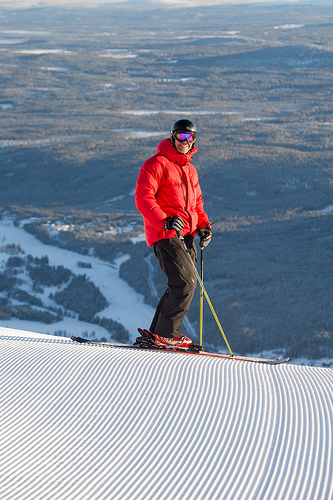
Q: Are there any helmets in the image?
A: Yes, there is a helmet.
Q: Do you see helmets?
A: Yes, there is a helmet.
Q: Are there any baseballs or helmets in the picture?
A: Yes, there is a helmet.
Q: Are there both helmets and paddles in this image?
A: No, there is a helmet but no paddles.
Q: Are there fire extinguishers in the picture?
A: No, there are no fire extinguishers.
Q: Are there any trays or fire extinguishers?
A: No, there are no fire extinguishers or trays.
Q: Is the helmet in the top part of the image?
A: Yes, the helmet is in the top of the image.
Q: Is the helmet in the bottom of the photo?
A: No, the helmet is in the top of the image.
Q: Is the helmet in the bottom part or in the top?
A: The helmet is in the top of the image.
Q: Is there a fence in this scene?
A: No, there are no fences.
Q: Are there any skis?
A: Yes, there are skis.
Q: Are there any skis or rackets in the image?
A: Yes, there are skis.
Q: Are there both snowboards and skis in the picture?
A: No, there are skis but no snowboards.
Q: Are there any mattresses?
A: No, there are no mattresses.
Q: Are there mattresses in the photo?
A: No, there are no mattresses.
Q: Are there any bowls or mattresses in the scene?
A: No, there are no mattresses or bowls.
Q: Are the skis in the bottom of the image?
A: Yes, the skis are in the bottom of the image.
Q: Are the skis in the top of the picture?
A: No, the skis are in the bottom of the image.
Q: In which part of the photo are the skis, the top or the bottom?
A: The skis are in the bottom of the image.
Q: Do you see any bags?
A: No, there are no bags.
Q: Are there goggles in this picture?
A: Yes, there are goggles.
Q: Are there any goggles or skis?
A: Yes, there are goggles.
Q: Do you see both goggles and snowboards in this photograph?
A: No, there are goggles but no snowboards.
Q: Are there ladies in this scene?
A: No, there are no ladies.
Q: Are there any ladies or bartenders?
A: No, there are no ladies or bartenders.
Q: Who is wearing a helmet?
A: The man is wearing a helmet.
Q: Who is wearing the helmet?
A: The man is wearing a helmet.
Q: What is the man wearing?
A: The man is wearing a helmet.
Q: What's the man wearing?
A: The man is wearing a helmet.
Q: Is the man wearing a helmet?
A: Yes, the man is wearing a helmet.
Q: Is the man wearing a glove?
A: No, the man is wearing a helmet.